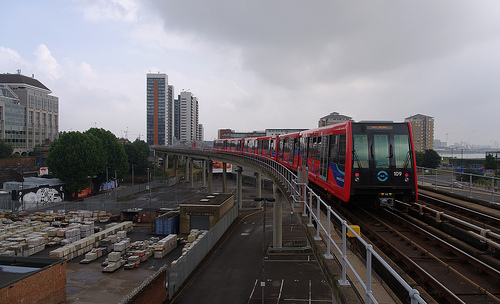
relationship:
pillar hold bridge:
[267, 181, 290, 251] [196, 128, 387, 283]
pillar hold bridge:
[245, 164, 266, 212] [196, 128, 387, 283]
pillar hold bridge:
[212, 154, 232, 194] [196, 128, 387, 283]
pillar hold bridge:
[182, 153, 203, 184] [196, 128, 387, 283]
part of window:
[328, 139, 346, 162] [355, 131, 422, 176]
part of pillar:
[269, 204, 282, 227] [218, 162, 232, 194]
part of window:
[352, 142, 372, 170] [349, 126, 416, 183]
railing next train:
[260, 143, 371, 273] [199, 112, 429, 206]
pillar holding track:
[218, 162, 232, 194] [152, 146, 500, 304]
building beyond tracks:
[136, 66, 177, 148] [143, 143, 498, 303]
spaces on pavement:
[262, 248, 312, 262] [126, 172, 338, 302]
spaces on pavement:
[308, 276, 334, 298] [126, 172, 338, 302]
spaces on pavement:
[278, 277, 312, 297] [126, 172, 338, 302]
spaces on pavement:
[249, 273, 281, 299] [126, 172, 338, 302]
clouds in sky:
[3, 1, 497, 152] [3, 5, 498, 137]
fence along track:
[321, 203, 421, 300] [152, 146, 500, 304]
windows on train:
[156, 112, 166, 116] [167, 109, 424, 223]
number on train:
[391, 168, 405, 179] [209, 116, 425, 215]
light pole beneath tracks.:
[250, 189, 290, 263] [265, 190, 495, 267]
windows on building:
[156, 82, 166, 116] [144, 73, 174, 147]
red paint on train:
[270, 131, 375, 203] [213, 120, 417, 201]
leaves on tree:
[57, 115, 114, 186] [55, 107, 163, 197]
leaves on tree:
[102, 123, 136, 165] [95, 124, 135, 183]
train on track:
[213, 120, 417, 201] [319, 190, 498, 301]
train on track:
[213, 120, 417, 201] [325, 173, 500, 302]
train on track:
[213, 120, 417, 201] [352, 203, 498, 290]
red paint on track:
[209, 121, 419, 198] [352, 203, 498, 290]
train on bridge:
[213, 120, 417, 201] [190, 101, 429, 291]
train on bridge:
[213, 120, 417, 201] [278, 187, 426, 279]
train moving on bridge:
[238, 114, 428, 201] [167, 131, 369, 291]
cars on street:
[1, 198, 204, 266] [1, 176, 221, 296]